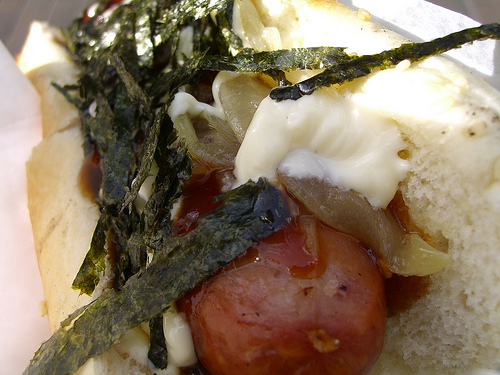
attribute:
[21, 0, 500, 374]
topping — green, leafy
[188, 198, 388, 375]
hotdog — juicy, plump, red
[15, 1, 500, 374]
bun — white, toasted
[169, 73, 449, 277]
onions — cooked, sauteed, white, clear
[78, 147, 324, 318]
sauce — brown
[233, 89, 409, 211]
mayo — white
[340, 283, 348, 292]
speck — black